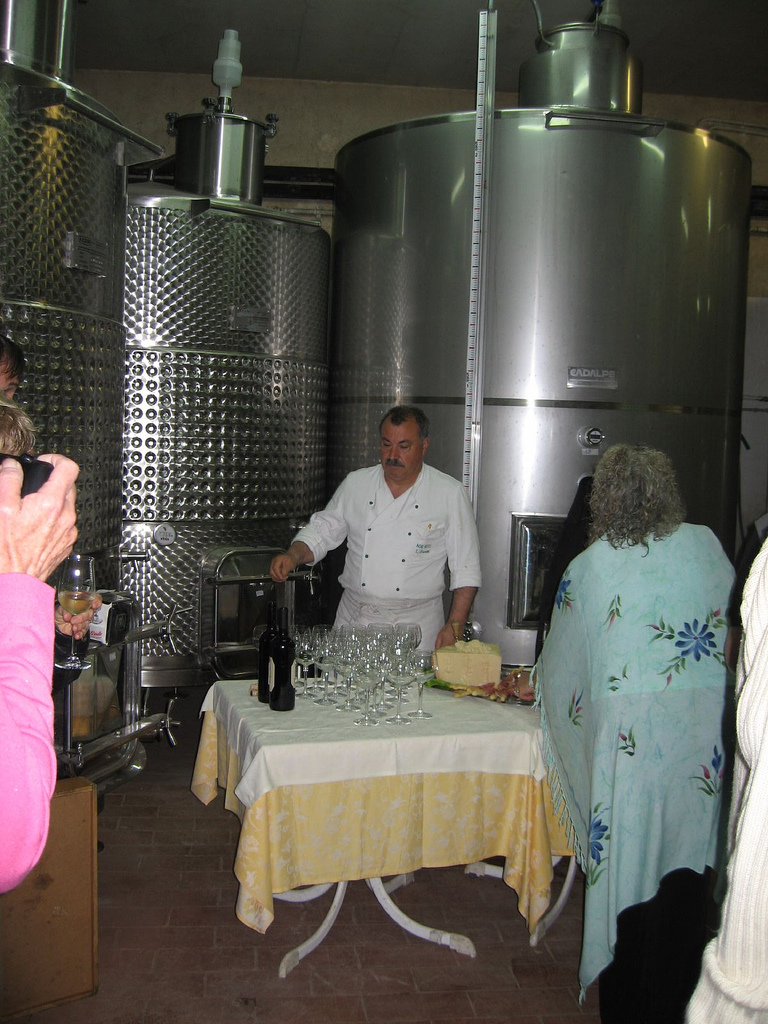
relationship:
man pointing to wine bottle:
[269, 404, 482, 736] [260, 608, 296, 709]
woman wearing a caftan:
[537, 446, 754, 1022] [603, 565, 674, 641]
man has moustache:
[259, 364, 510, 735] [376, 452, 417, 467]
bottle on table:
[267, 608, 296, 711] [162, 660, 568, 968]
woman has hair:
[521, 404, 734, 976] [576, 423, 687, 579]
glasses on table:
[296, 587, 476, 754] [162, 660, 568, 968]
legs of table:
[239, 860, 468, 1024] [162, 660, 568, 968]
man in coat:
[269, 404, 482, 736] [275, 459, 478, 632]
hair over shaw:
[587, 427, 686, 556] [527, 559, 739, 990]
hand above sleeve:
[3, 427, 96, 569] [2, 565, 62, 925]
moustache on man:
[385, 459, 407, 468] [270, 396, 493, 729]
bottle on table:
[249, 586, 334, 713] [162, 660, 568, 968]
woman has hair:
[537, 446, 754, 1022] [576, 438, 698, 556]